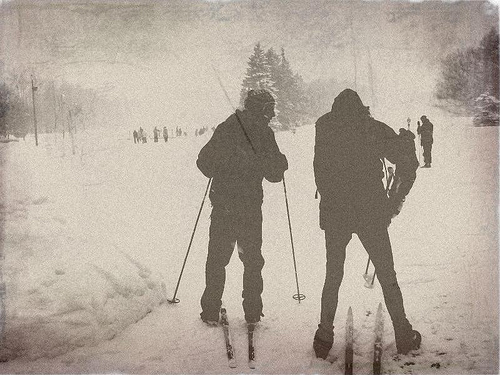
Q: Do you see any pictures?
A: No, there are no pictures.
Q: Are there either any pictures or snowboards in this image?
A: No, there are no pictures or snowboards.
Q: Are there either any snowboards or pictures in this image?
A: No, there are no pictures or snowboards.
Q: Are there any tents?
A: No, there are no tents.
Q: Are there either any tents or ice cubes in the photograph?
A: No, there are no tents or ice cubes.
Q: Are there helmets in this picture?
A: No, there are no helmets.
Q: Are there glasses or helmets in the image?
A: No, there are no helmets or glasses.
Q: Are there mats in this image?
A: No, there are no mats.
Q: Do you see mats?
A: No, there are no mats.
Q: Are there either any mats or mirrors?
A: No, there are no mats or mirrors.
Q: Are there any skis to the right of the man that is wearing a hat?
A: Yes, there is a ski to the right of the man.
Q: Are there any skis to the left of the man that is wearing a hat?
A: No, the ski is to the right of the man.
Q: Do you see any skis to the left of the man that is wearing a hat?
A: No, the ski is to the right of the man.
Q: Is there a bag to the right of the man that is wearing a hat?
A: No, there is a ski to the right of the man.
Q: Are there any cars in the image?
A: No, there are no cars.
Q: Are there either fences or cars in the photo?
A: No, there are no cars or fences.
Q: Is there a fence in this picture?
A: No, there are no fences.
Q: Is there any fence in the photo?
A: No, there are no fences.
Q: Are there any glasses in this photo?
A: No, there are no glasses.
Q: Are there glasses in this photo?
A: No, there are no glasses.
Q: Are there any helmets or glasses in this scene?
A: No, there are no glasses or helmets.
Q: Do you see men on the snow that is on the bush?
A: Yes, there is a man on the snow.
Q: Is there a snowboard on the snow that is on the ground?
A: No, there is a man on the snow.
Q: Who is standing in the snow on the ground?
A: The man is standing in the snow.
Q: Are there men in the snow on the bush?
A: Yes, there is a man in the snow.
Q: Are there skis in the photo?
A: Yes, there are skis.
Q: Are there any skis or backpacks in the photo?
A: Yes, there are skis.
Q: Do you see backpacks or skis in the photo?
A: Yes, there are skis.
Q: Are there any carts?
A: No, there are no carts.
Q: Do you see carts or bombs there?
A: No, there are no carts or bombs.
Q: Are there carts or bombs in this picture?
A: No, there are no carts or bombs.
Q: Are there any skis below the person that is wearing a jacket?
A: Yes, there are skis below the person.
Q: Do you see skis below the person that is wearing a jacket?
A: Yes, there are skis below the person.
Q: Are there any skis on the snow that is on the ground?
A: Yes, there are skis on the snow.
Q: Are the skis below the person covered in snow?
A: Yes, the skis are covered in snow.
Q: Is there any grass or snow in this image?
A: Yes, there is snow.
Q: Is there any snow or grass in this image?
A: Yes, there is snow.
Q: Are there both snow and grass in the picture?
A: No, there is snow but no grass.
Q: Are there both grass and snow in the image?
A: No, there is snow but no grass.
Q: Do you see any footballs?
A: No, there are no footballs.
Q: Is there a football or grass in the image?
A: No, there are no footballs or grass.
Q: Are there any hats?
A: Yes, there is a hat.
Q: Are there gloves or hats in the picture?
A: Yes, there is a hat.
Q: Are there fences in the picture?
A: No, there are no fences.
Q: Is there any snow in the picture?
A: Yes, there is snow.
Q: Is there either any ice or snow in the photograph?
A: Yes, there is snow.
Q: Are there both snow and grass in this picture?
A: No, there is snow but no grass.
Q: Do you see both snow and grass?
A: No, there is snow but no grass.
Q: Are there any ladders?
A: No, there are no ladders.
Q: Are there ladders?
A: No, there are no ladders.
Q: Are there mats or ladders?
A: No, there are no ladders or mats.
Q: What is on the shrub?
A: The snow is on the shrub.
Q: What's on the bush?
A: The snow is on the shrub.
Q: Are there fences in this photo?
A: No, there are no fences.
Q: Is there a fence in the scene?
A: No, there are no fences.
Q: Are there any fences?
A: No, there are no fences.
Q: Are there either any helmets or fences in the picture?
A: No, there are no fences or helmets.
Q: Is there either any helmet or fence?
A: No, there are no fences or helmets.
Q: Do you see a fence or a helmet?
A: No, there are no fences or helmets.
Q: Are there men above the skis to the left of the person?
A: Yes, there is a man above the skis.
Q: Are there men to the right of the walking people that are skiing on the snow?
A: Yes, there is a man to the right of the people.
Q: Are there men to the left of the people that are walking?
A: No, the man is to the right of the people.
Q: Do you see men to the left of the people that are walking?
A: No, the man is to the right of the people.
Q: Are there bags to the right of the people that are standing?
A: No, there is a man to the right of the people.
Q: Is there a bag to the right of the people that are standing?
A: No, there is a man to the right of the people.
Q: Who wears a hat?
A: The man wears a hat.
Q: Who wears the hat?
A: The man wears a hat.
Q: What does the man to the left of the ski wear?
A: The man wears a hat.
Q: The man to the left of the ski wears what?
A: The man wears a hat.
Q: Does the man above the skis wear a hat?
A: Yes, the man wears a hat.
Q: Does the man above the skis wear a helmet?
A: No, the man wears a hat.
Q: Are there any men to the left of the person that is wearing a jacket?
A: Yes, there is a man to the left of the person.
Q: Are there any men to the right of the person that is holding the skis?
A: No, the man is to the left of the person.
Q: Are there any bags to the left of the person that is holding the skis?
A: No, there is a man to the left of the person.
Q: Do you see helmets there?
A: No, there are no helmets.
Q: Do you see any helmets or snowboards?
A: No, there are no helmets or snowboards.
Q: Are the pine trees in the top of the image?
A: Yes, the pine trees are in the top of the image.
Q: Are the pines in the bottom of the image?
A: No, the pines are in the top of the image.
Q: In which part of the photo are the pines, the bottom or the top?
A: The pines are in the top of the image.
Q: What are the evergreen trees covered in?
A: The pine trees are covered in snow.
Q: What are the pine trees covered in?
A: The pine trees are covered in snow.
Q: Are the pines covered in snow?
A: Yes, the pines are covered in snow.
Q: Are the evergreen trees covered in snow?
A: Yes, the pines are covered in snow.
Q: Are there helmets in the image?
A: No, there are no helmets.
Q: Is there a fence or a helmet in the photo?
A: No, there are no helmets or fences.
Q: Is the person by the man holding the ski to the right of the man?
A: Yes, the person is holding the ski.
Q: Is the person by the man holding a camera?
A: No, the person is holding the ski.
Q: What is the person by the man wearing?
A: The person is wearing a jacket.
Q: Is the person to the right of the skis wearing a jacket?
A: Yes, the person is wearing a jacket.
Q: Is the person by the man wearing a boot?
A: No, the person is wearing a jacket.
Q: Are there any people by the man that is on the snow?
A: Yes, there is a person by the man.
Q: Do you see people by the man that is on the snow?
A: Yes, there is a person by the man.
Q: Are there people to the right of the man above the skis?
A: Yes, there is a person to the right of the man.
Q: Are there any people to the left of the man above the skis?
A: No, the person is to the right of the man.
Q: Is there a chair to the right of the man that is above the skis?
A: No, there is a person to the right of the man.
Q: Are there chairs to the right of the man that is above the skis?
A: No, there is a person to the right of the man.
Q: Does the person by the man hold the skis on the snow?
A: Yes, the person holds the skis.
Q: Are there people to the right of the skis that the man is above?
A: Yes, there is a person to the right of the skis.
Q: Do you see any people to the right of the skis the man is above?
A: Yes, there is a person to the right of the skis.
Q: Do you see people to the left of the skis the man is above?
A: No, the person is to the right of the skis.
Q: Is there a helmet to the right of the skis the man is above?
A: No, there is a person to the right of the skis.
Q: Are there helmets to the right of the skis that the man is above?
A: No, there is a person to the right of the skis.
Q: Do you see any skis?
A: Yes, there are skis.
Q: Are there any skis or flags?
A: Yes, there are skis.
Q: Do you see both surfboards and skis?
A: No, there are skis but no surfboards.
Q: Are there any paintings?
A: No, there are no paintings.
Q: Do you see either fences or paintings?
A: No, there are no paintings or fences.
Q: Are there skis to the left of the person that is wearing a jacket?
A: Yes, there are skis to the left of the person.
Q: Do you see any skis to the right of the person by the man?
A: No, the skis are to the left of the person.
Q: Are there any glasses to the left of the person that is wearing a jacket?
A: No, there are skis to the left of the person.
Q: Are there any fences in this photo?
A: No, there are no fences.